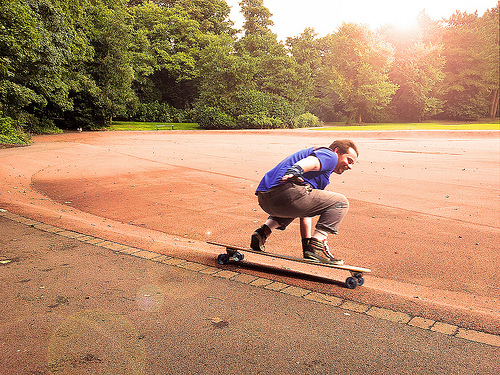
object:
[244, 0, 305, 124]
trees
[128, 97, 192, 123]
brush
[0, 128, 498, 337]
road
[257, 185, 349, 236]
pants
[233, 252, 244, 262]
wheel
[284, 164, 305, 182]
fingerless gloves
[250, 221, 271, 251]
boot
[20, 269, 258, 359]
pavement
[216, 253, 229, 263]
wheels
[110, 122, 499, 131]
lawn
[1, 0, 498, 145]
forest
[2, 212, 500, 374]
street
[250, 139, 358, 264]
man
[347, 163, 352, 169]
nose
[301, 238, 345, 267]
big boot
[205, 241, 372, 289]
skateboard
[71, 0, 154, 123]
trees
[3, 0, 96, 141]
trees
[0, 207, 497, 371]
bricks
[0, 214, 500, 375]
sidewalk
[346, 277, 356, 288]
wheel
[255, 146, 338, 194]
shirt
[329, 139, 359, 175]
head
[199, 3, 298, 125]
tree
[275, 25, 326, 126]
tree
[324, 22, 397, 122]
tree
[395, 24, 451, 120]
tree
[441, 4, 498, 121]
tree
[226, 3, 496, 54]
sky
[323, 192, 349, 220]
knee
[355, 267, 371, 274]
nose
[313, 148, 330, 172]
cuffs